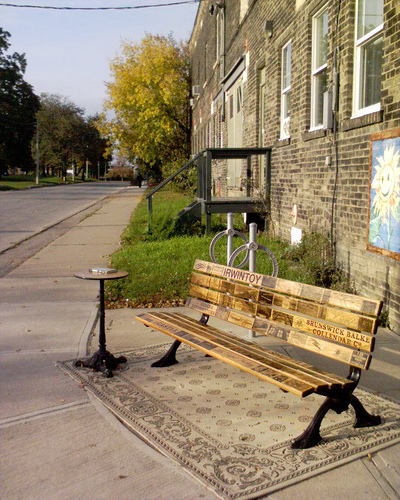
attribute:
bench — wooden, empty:
[131, 259, 385, 451]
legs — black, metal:
[287, 393, 381, 450]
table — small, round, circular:
[71, 269, 132, 379]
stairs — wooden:
[158, 198, 203, 236]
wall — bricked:
[184, 1, 399, 342]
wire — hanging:
[2, 1, 200, 13]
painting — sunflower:
[363, 125, 399, 261]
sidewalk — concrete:
[4, 187, 236, 499]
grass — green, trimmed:
[106, 232, 311, 298]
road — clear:
[0, 177, 140, 280]